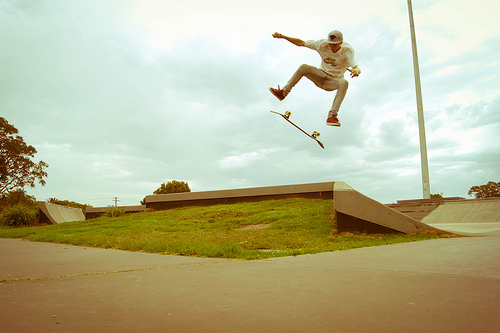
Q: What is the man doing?
A: Skateboarding.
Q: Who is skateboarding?
A: The man.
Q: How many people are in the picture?
A: One.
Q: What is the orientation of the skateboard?
A: Upside Down.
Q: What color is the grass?
A: Green.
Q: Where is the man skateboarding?
A: A skate ramp.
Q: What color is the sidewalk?
A: Tan.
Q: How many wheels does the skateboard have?
A: Four.